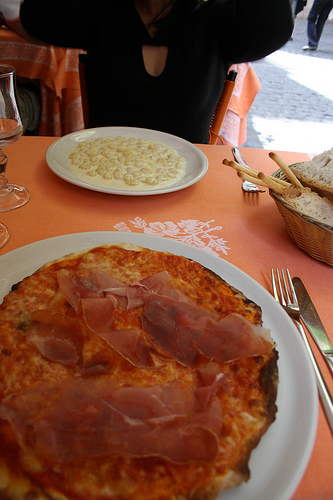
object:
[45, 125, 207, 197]
plate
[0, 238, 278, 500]
pizza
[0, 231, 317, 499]
bowl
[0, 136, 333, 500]
table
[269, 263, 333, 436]
fork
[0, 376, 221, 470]
ham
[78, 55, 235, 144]
chair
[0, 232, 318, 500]
plate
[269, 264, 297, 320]
tines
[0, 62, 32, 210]
glass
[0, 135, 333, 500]
tablecloth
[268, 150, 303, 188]
bread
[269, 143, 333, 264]
basket